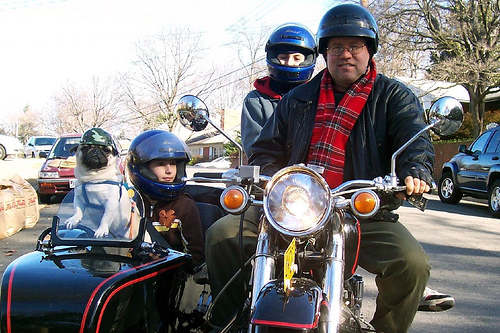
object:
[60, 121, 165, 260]
dog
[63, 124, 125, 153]
helmet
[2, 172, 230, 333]
sidecar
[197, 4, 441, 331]
man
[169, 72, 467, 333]
motorcycle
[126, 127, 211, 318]
child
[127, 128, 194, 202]
helmet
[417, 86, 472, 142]
mirror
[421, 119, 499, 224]
suv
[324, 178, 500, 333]
street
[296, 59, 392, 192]
scarf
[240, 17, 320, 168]
passenger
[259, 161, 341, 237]
headlight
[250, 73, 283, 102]
hoodie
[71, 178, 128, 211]
harness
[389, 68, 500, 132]
house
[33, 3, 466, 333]
family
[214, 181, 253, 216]
turnsignals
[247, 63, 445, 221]
jacket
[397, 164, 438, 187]
gloves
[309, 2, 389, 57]
helmet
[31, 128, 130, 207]
car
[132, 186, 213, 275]
jacket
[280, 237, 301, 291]
plate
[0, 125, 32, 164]
suv